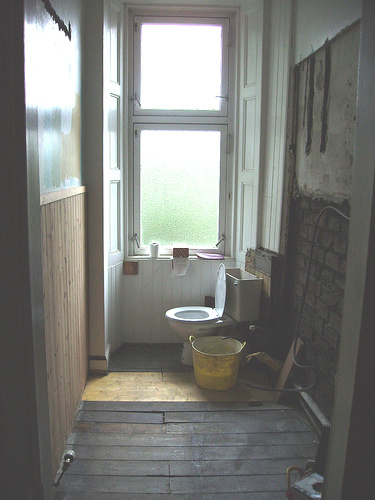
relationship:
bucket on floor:
[177, 334, 254, 398] [61, 342, 329, 499]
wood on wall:
[29, 186, 92, 499] [4, 0, 95, 500]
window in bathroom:
[126, 10, 231, 264] [3, 0, 374, 499]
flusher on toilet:
[225, 282, 244, 290] [166, 262, 261, 370]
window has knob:
[126, 10, 231, 264] [214, 93, 227, 101]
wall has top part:
[4, 0, 95, 500] [23, 1, 97, 198]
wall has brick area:
[277, 2, 359, 434] [275, 189, 350, 436]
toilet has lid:
[166, 262, 261, 370] [210, 262, 228, 316]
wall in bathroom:
[4, 0, 95, 500] [3, 0, 374, 499]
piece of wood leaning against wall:
[269, 336, 303, 404] [277, 2, 359, 434]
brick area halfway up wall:
[275, 189, 350, 436] [277, 2, 359, 434]